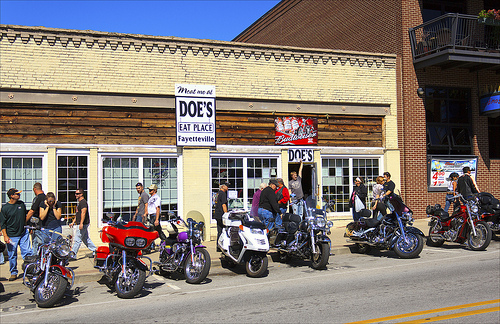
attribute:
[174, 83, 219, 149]
sign — white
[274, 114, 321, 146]
sign — red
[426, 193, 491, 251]
motorcycle — red, parked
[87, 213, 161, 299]
motorcycle — red, parked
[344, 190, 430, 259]
motorcycle — parked, blue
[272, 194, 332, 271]
motorcycle — parked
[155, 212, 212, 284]
motorcycle — parked, purple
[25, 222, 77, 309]
motorcycle — parked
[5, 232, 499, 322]
road — paved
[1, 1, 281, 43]
sky — blue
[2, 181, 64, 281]
people — standing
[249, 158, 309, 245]
people — standing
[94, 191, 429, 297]
motorcycles — parked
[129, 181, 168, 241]
people — walking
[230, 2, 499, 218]
building — brick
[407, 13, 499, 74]
patio — black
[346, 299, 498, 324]
lines — painted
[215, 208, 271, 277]
motorcycle — white